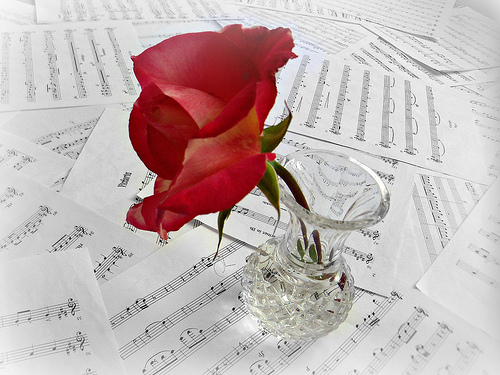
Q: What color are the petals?
A: Red.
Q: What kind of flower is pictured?
A: Rose.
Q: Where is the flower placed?
A: In a vase.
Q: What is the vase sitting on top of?
A: Sheet music.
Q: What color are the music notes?
A: Black.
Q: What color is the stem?
A: Green.